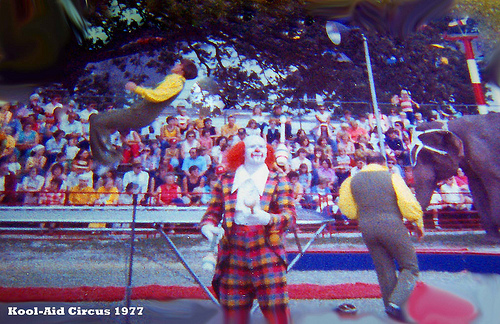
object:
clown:
[192, 126, 316, 323]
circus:
[1, 4, 2, 5]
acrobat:
[75, 46, 204, 174]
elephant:
[404, 105, 500, 245]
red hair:
[218, 140, 280, 172]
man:
[326, 145, 432, 323]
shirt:
[328, 161, 431, 229]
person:
[66, 173, 97, 208]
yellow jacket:
[65, 185, 99, 209]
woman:
[148, 173, 188, 204]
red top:
[154, 183, 179, 205]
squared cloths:
[198, 168, 301, 323]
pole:
[437, 6, 496, 117]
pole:
[354, 29, 394, 158]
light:
[320, 14, 357, 47]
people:
[0, 90, 473, 214]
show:
[76, 44, 499, 319]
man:
[65, 158, 95, 183]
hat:
[71, 158, 92, 172]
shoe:
[373, 299, 419, 324]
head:
[399, 116, 466, 194]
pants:
[215, 222, 295, 324]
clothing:
[334, 161, 430, 321]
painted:
[240, 129, 269, 166]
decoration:
[399, 125, 448, 168]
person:
[117, 158, 153, 190]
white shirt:
[119, 173, 154, 194]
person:
[33, 175, 70, 211]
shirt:
[35, 187, 70, 206]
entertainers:
[78, 54, 441, 324]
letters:
[4, 301, 151, 321]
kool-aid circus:
[7, 305, 114, 324]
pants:
[355, 213, 428, 305]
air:
[2, 3, 482, 200]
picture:
[3, 3, 494, 323]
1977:
[113, 302, 150, 322]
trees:
[67, 3, 484, 91]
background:
[0, 1, 499, 94]